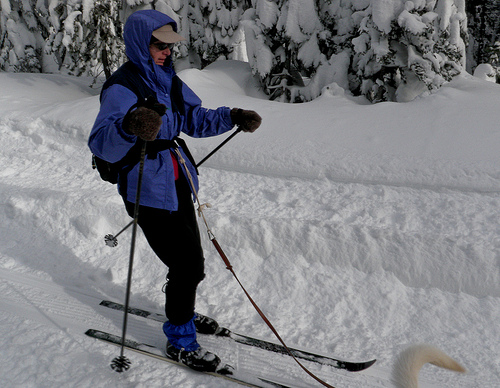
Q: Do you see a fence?
A: No, there are no fences.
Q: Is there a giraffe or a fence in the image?
A: No, there are no fences or giraffes.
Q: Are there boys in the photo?
A: No, there are no boys.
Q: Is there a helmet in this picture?
A: No, there are no helmets.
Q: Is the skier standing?
A: Yes, the skier is standing.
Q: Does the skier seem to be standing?
A: Yes, the skier is standing.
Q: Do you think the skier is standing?
A: Yes, the skier is standing.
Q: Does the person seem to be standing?
A: Yes, the skier is standing.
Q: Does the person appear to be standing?
A: Yes, the skier is standing.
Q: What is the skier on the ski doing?
A: The skier is standing.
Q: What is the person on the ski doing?
A: The skier is standing.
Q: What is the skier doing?
A: The skier is standing.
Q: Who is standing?
A: The skier is standing.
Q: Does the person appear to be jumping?
A: No, the skier is standing.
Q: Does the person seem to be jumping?
A: No, the skier is standing.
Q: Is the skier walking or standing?
A: The skier is standing.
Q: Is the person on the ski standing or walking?
A: The skier is standing.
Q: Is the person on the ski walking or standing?
A: The skier is standing.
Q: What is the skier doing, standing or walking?
A: The skier is standing.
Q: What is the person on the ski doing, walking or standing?
A: The skier is standing.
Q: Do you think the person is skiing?
A: Yes, the skier is skiing.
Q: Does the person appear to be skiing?
A: Yes, the skier is skiing.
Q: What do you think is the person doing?
A: The skier is skiing.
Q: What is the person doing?
A: The skier is skiing.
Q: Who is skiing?
A: The skier is skiing.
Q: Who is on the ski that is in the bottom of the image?
A: The skier is on the ski.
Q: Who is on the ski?
A: The skier is on the ski.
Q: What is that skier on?
A: The skier is on the ski.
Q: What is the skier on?
A: The skier is on the ski.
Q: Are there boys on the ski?
A: No, there is a skier on the ski.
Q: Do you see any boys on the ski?
A: No, there is a skier on the ski.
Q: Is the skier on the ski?
A: Yes, the skier is on the ski.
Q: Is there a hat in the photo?
A: Yes, there is a hat.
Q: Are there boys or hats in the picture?
A: Yes, there is a hat.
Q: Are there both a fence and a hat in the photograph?
A: No, there is a hat but no fences.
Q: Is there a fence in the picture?
A: No, there are no fences.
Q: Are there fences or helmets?
A: No, there are no fences or helmets.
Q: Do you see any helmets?
A: No, there are no helmets.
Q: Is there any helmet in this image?
A: No, there are no helmets.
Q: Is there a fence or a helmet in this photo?
A: No, there are no helmets or fences.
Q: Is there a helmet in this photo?
A: No, there are no helmets.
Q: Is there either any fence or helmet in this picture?
A: No, there are no helmets or fences.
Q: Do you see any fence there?
A: No, there are no fences.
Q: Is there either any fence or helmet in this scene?
A: No, there are no fences or helmets.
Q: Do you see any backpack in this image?
A: Yes, there is a backpack.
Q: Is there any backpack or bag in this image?
A: Yes, there is a backpack.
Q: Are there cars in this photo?
A: No, there are no cars.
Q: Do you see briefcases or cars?
A: No, there are no cars or briefcases.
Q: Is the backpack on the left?
A: Yes, the backpack is on the left of the image.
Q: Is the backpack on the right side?
A: No, the backpack is on the left of the image.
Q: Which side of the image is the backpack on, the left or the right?
A: The backpack is on the left of the image.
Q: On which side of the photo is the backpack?
A: The backpack is on the left of the image.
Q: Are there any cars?
A: No, there are no cars.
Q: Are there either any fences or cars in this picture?
A: No, there are no cars or fences.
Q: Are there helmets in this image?
A: No, there are no helmets.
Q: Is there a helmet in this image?
A: No, there are no helmets.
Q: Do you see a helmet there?
A: No, there are no helmets.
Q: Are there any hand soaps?
A: No, there are no hand soaps.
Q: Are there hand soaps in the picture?
A: No, there are no hand soaps.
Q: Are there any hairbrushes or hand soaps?
A: No, there are no hand soaps or hairbrushes.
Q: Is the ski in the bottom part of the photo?
A: Yes, the ski is in the bottom of the image.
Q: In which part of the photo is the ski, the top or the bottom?
A: The ski is in the bottom of the image.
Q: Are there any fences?
A: No, there are no fences.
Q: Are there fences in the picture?
A: No, there are no fences.